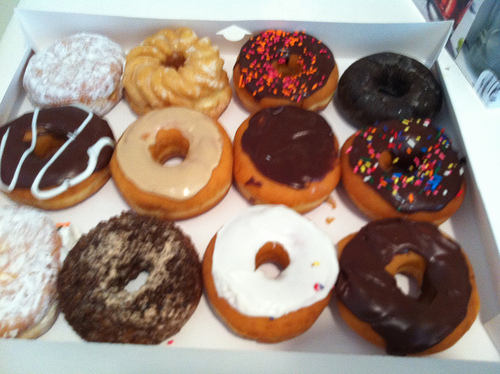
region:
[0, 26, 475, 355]
a dozen different donuts in a box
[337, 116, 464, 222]
donut with chocolate frosting and rainbow sprinkles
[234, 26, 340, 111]
donut with chocolate frosting and red sprinkles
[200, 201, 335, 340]
donut with white frosting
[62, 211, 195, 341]
chocolate donut with glaze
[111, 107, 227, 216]
donut with maple frosting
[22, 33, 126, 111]
jelly donut with powder sugar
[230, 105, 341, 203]
cream filled donut with chocolate frosting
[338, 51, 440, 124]
donut dipped in dark chocolate frosting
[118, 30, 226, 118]
glaze donut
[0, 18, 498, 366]
one dozen fresh donuts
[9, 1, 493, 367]
a dozen donuts in white box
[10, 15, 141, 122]
confectioner sugar powder covering donut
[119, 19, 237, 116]
crueller type donut with glaze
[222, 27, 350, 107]
chocolate frosted donut with orange and pink sprinkles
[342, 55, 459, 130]
chocolate cake donut with glaze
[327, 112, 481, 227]
chocolate frosted donut with blue, yellow, pink, white, and orange sprinkles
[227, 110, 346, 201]
chocolate frosted donut with no hole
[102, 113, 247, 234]
maple frosting on donut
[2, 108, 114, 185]
white swirl on chocolate frosting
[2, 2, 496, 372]
This is a box of doughnuts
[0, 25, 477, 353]
Twelve doughnuts are inside the box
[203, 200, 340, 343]
This doughnut has white icing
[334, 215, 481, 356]
This doughnut has chocolate frosting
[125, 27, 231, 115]
This is a cruller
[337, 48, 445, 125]
This is a chocolate doughnut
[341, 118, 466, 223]
This doughnut has sprinkles on it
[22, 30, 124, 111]
A filled doughnut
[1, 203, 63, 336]
This doughnut is covered in powdered sugar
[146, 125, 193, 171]
A hole is in the center of the doughnut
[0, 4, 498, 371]
A dozen donuts in a box.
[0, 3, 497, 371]
The box is white.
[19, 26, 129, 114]
The donut is round.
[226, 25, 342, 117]
The donut is round.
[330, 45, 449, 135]
The donut is round.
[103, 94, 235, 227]
The donut is round.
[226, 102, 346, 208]
The donut is round.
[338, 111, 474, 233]
The donut is round.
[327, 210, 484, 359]
The donut is round.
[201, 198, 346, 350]
The donut is round.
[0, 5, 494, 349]
a dozen doughnuts in a box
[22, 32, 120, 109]
a powdered doughnut in a box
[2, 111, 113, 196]
a chocolate covered doughnut with a drizzle of white frosting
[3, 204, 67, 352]
a white powdered doughnut in a box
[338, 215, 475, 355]
a doughnut with chocolate frosting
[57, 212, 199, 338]
a chocolate covered doughnut in a box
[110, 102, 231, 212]
a caramel frosted doughtnut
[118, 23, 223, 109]
a glazed covered doughnut in a box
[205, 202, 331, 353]
a doughnut with white frosting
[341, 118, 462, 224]
a doughnut with chocolate frosting and sprinkles